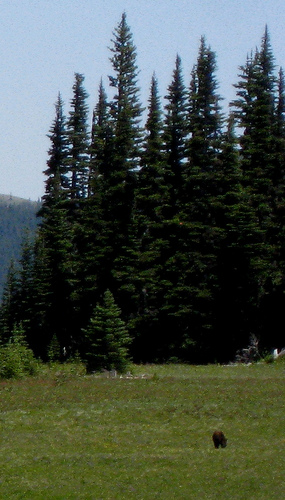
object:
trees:
[0, 8, 285, 378]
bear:
[212, 429, 228, 449]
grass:
[0, 357, 285, 499]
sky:
[0, 0, 285, 115]